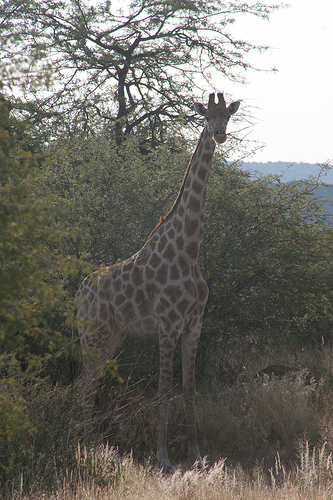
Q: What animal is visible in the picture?
A: Giraffe.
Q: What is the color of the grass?
A: Light brown.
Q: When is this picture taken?
A: On a sunny day.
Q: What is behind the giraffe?
A: Bushes and a tree.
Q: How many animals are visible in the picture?
A: One.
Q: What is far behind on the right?
A: Mountain.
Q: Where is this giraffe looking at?
A: Towards camera.